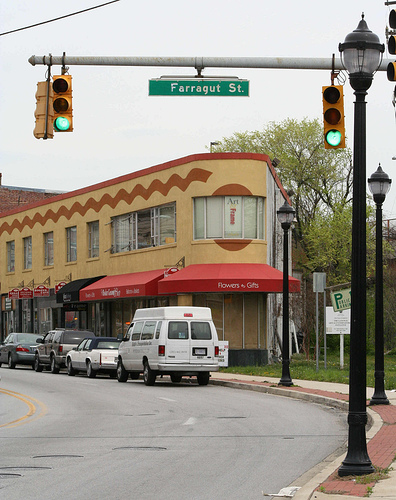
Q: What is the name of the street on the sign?
A: Farragut St.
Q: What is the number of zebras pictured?
A: Zero.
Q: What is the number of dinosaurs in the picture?
A: Zero.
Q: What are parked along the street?
A: Vehicles.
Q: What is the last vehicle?
A: A van.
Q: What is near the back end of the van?
A: A black light post.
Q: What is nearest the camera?
A: A black light post.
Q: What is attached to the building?
A: A red awning.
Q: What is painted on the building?
A: A wavy line.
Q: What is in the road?
A: Four manhole covers.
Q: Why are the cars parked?
A: They are not in use.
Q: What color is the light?
A: Green.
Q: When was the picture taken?
A: In the daytime.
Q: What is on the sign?
A: Farragut St.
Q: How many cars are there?
A: 4.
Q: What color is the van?
A: White.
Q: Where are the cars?
A: Parked at the curb.